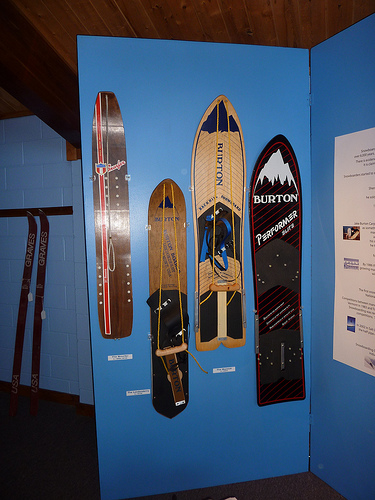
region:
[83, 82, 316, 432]
four skateboards hanging from a board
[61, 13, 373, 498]
two-fold blue board holding skateboards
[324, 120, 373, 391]
a white paper on blue board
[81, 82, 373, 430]
white paper has information of skateboards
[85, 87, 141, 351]
a skateboard color brown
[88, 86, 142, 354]
skateboard has a red line on left side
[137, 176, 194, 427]
the skateboard has a yellow thread on top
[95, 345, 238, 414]
white rectangular labels on blue board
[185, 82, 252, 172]
nose of a skateboard is pointy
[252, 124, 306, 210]
a paint of a mountain is on skateboard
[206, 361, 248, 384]
white labels on the wall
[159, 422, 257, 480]
dark blue wall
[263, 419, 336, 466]
corner of the blue wall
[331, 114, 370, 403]
white poster on the wall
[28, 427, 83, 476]
black ground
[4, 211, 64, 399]
ski's on the wall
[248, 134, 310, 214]
mountain tops on the snowboard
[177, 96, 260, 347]
brown snowboard hanging on the wall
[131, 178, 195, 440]
dark brown and black snowboard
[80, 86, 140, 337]
dark brown and red snowboard on the wall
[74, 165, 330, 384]
picture taken indoors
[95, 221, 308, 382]
various snow boards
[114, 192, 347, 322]
the boards are on a wall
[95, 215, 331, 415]
the wall is medium blue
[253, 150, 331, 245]
a board has the word Burton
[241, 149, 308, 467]
the board is white black and red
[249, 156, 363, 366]
the board says Performer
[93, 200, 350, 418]
the boards are on the wall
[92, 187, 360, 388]
Four snow boards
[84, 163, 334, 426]
the boards are on display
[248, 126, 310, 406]
Burton Performer barnd snow board.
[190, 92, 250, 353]
Ripton brand snowboard on wall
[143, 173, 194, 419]
Barton snowboard displayed on wall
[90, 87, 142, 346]
Snowboard on display on store wall.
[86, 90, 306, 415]
Group of four snowboards displayed on blue store wall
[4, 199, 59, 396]
Snow skis upright against cement block wall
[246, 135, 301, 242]
"Burton Performer" words and logo on snow board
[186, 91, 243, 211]
"Ripton" words and logo on snowboard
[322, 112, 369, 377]
Portion of wordy poster displayed obliquely on wall.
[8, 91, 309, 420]
Snow equipment sales store display.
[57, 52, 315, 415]
snowboards displayed on the wall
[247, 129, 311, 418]
the a black and red board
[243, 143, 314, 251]
there are red lines on the board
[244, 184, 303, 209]
the letters are white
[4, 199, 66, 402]
skis leaning on the wall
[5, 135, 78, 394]
the wall is blue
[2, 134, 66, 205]
the wall is made with blocks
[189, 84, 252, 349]
the snowboard is tan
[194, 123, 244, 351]
the board is made of wood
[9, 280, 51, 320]
white tags on the skis